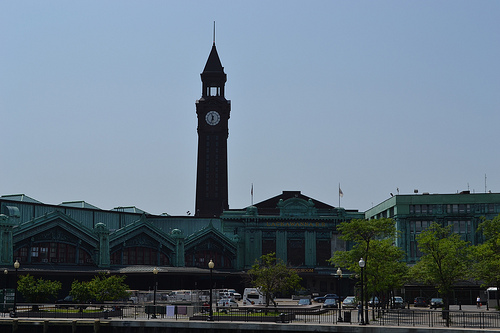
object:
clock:
[205, 111, 220, 126]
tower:
[195, 20, 232, 218]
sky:
[0, 0, 498, 214]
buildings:
[0, 20, 231, 307]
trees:
[406, 215, 495, 326]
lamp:
[359, 257, 366, 268]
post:
[359, 267, 366, 325]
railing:
[279, 308, 500, 329]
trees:
[326, 215, 413, 326]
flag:
[339, 183, 344, 199]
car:
[429, 298, 446, 310]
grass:
[196, 311, 286, 322]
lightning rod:
[212, 21, 216, 47]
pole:
[252, 183, 254, 206]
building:
[230, 190, 365, 298]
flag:
[251, 184, 254, 199]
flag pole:
[339, 182, 341, 216]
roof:
[240, 191, 338, 214]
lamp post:
[358, 257, 368, 324]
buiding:
[365, 190, 500, 305]